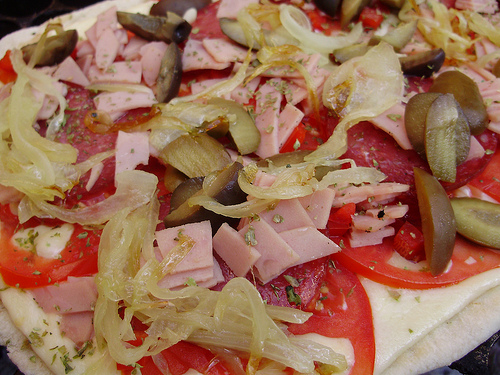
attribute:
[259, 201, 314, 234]
meat piece — small, pink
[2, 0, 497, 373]
panini — good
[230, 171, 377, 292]
meat — diced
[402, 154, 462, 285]
artichoke — cooked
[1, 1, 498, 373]
food — different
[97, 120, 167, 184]
meat piece — small, pink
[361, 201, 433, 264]
red peppers — diced, small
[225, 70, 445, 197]
red peppers — small, diced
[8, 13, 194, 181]
red peppers — small, diced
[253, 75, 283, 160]
meat — small, pink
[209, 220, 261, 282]
meat — pink, small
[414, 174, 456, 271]
olives — diced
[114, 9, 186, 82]
mushrooms — diced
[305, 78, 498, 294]
tomatoes — bright red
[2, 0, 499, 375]
meat — small, pink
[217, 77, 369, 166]
dog — Big 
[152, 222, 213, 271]
meat — small, pink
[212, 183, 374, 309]
meat — pink, small